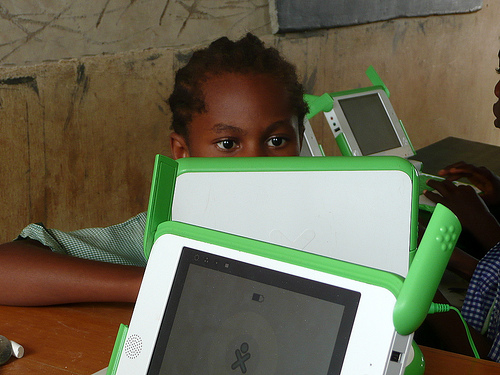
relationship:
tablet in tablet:
[110, 218, 414, 374] [108, 218, 414, 374]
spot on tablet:
[369, 363, 373, 368] [110, 218, 414, 374]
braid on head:
[170, 92, 203, 107] [170, 34, 308, 161]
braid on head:
[173, 66, 203, 84] [170, 34, 308, 161]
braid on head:
[189, 52, 217, 72] [170, 34, 308, 161]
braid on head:
[213, 36, 235, 70] [170, 34, 308, 161]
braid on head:
[239, 33, 261, 64] [170, 34, 308, 161]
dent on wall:
[1, 74, 41, 91] [0, 1, 496, 245]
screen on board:
[273, 0, 488, 36] [1, 0, 499, 64]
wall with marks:
[0, 1, 496, 245] [0, 0, 271, 61]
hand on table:
[421, 176, 486, 223] [393, 137, 498, 215]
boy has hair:
[0, 33, 396, 306] [170, 34, 308, 161]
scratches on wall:
[0, 0, 271, 61] [0, 1, 496, 245]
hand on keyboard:
[421, 176, 486, 223] [417, 173, 444, 199]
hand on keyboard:
[443, 164, 499, 205] [417, 173, 444, 199]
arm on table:
[0, 232, 146, 306] [0, 251, 499, 372]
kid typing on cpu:
[412, 46, 498, 358] [326, 61, 482, 213]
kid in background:
[412, 46, 498, 358] [0, 1, 496, 245]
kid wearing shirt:
[0, 33, 396, 306] [27, 178, 379, 266]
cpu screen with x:
[151, 265, 343, 374] [230, 351, 252, 373]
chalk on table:
[10, 340, 24, 358] [0, 251, 499, 372]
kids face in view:
[170, 34, 308, 161] [0, 1, 496, 245]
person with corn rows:
[0, 33, 396, 306] [170, 34, 308, 161]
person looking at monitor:
[0, 33, 396, 306] [145, 156, 424, 293]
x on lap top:
[230, 351, 252, 373] [110, 218, 414, 374]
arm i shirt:
[0, 232, 146, 306] [27, 178, 379, 266]